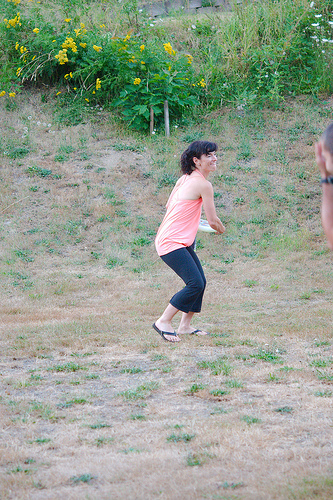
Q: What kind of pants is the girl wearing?
A: Capri's.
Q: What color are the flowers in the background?
A: Yellow.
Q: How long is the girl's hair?
A: Shoulder Length.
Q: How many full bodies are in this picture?
A: One.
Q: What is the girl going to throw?
A: Frisbee.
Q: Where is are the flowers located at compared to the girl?
A: Behind.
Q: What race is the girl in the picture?
A: White.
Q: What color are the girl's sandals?
A: Black.